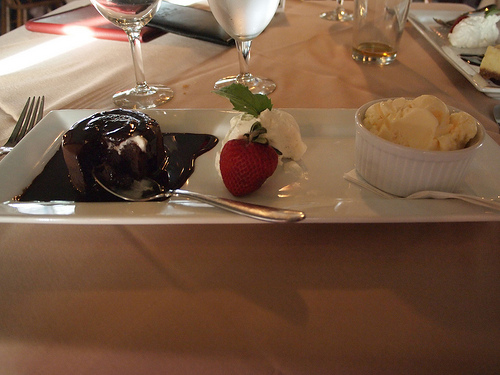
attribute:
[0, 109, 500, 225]
platter — ceramic, rectangular, white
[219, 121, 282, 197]
strawberry — red, ripe, juicy, large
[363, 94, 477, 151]
ice cream — vanilla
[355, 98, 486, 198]
bowl — ramekin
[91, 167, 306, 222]
spoon — silver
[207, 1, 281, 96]
water glass — cold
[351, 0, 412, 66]
glass — empty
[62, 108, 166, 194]
chocolate cake — chocolate lava cake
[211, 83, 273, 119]
mint leaf — green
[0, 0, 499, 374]
tablecloth — beige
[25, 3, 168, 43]
tablet — red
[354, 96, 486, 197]
ramekin — white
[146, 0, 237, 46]
case — black